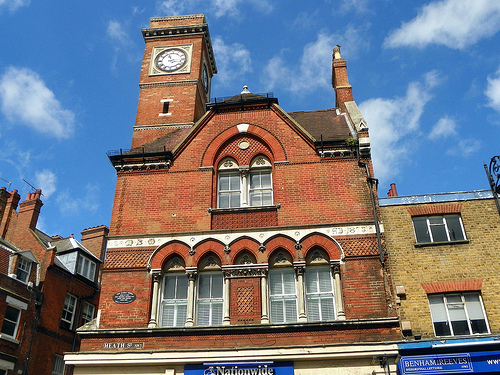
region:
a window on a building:
[155, 269, 192, 326]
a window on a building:
[190, 267, 227, 331]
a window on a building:
[265, 266, 301, 323]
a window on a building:
[303, 262, 341, 324]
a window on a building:
[213, 168, 243, 211]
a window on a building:
[244, 166, 276, 207]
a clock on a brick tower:
[147, 44, 194, 74]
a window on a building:
[423, 287, 493, 338]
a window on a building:
[405, 203, 472, 247]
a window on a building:
[56, 292, 77, 332]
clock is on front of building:
[149, 43, 194, 73]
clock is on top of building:
[149, 40, 190, 78]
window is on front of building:
[212, 151, 245, 211]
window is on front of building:
[410, 210, 468, 249]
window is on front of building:
[423, 285, 489, 337]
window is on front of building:
[264, 261, 297, 324]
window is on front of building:
[300, 260, 337, 325]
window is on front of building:
[192, 270, 228, 329]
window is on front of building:
[156, 271, 185, 326]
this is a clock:
[132, 42, 199, 79]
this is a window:
[214, 155, 249, 209]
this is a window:
[250, 162, 272, 210]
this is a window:
[160, 276, 185, 328]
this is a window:
[181, 239, 246, 341]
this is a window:
[269, 260, 304, 328]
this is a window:
[301, 260, 332, 322]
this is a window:
[413, 200, 466, 245]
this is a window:
[426, 287, 493, 347]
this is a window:
[75, 242, 102, 287]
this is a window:
[16, 257, 30, 287]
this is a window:
[55, 290, 80, 327]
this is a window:
[193, 267, 223, 330]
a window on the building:
[414, 216, 448, 237]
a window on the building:
[426, 308, 471, 330]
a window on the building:
[273, 256, 290, 316]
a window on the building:
[195, 262, 231, 325]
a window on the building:
[158, 262, 192, 319]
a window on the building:
[255, 167, 268, 212]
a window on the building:
[217, 171, 244, 213]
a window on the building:
[73, 241, 105, 281]